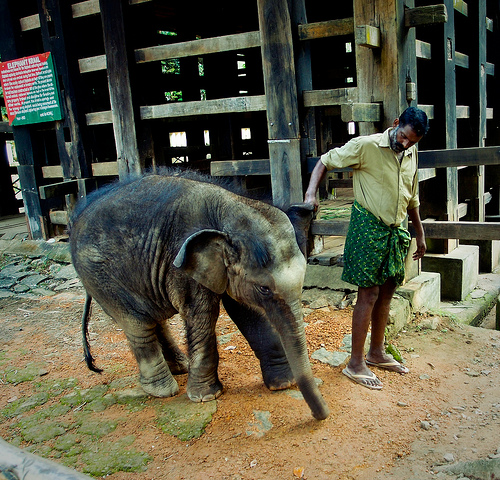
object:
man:
[47, 97, 453, 434]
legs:
[177, 299, 298, 404]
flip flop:
[366, 352, 408, 373]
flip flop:
[338, 362, 383, 392]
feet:
[345, 351, 410, 387]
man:
[302, 109, 437, 391]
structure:
[2, 0, 498, 298]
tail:
[72, 286, 105, 381]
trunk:
[256, 299, 328, 423]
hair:
[399, 104, 431, 139]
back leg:
[124, 320, 177, 411]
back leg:
[151, 320, 192, 372]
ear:
[174, 232, 237, 295]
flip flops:
[341, 352, 411, 394]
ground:
[0, 232, 499, 478]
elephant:
[68, 174, 331, 423]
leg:
[168, 282, 226, 402]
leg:
[223, 294, 293, 389]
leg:
[150, 319, 190, 376]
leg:
[90, 278, 178, 397]